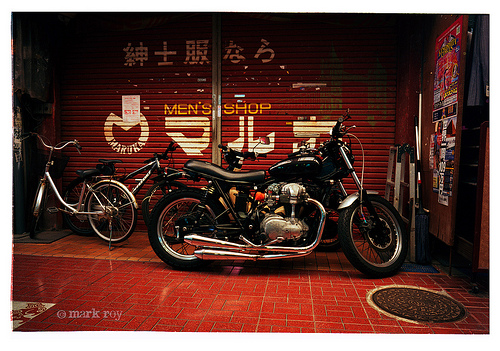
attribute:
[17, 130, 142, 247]
bicycle — here, silver, black, parked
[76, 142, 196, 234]
bicycle — here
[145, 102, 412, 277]
motorcycle — here, black, chrome, silver, parked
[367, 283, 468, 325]
man hole cover — brown, round, metal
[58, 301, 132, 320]
name — photographer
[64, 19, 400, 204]
door — red, metal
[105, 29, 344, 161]
writing — white, chinese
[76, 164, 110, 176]
seat — black, motorcycle's, leather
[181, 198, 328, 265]
muffler — chrome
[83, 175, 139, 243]
tire — silver, black, round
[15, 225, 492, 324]
bricks — red, shiny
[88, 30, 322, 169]
sign — red, yellow, white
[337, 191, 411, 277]
tire — black, inflated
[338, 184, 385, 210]
fender — silver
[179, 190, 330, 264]
exhaust — chome, motorcycle's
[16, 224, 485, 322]
flooring — tiled, ceramic, red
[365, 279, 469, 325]
man hole covering — here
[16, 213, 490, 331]
floor — red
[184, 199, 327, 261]
pipes — exhaust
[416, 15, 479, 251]
garage door — red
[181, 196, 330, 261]
exhaust pipes — metal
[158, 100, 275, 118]
lettering — yellow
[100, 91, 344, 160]
symbol — white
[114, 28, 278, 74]
symbols — foreign, white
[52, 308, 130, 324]
watermark — mark roy